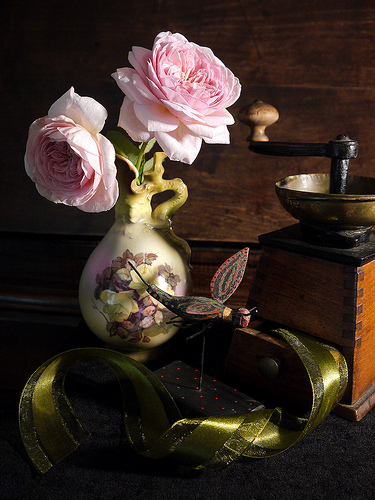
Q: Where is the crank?
A: To the right of the flower.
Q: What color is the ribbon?
A: Green.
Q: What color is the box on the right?
A: Brown.